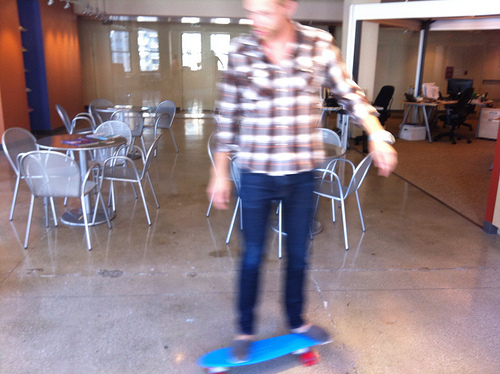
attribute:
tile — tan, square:
[344, 269, 389, 304]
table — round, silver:
[39, 135, 146, 179]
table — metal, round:
[93, 103, 158, 158]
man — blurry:
[203, 0, 398, 362]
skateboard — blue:
[195, 332, 320, 372]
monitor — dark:
[445, 75, 475, 97]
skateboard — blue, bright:
[178, 287, 369, 360]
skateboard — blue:
[192, 333, 339, 369]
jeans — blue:
[185, 164, 359, 340]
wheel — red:
[296, 347, 326, 367]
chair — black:
[435, 88, 475, 143]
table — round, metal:
[30, 124, 129, 234]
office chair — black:
[428, 82, 479, 146]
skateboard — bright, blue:
[192, 316, 332, 371]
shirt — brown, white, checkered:
[201, 17, 393, 194]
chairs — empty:
[3, 95, 180, 254]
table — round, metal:
[232, 167, 317, 340]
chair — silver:
[103, 128, 170, 228]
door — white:
[178, 27, 230, 120]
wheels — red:
[282, 349, 321, 369]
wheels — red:
[203, 361, 229, 371]